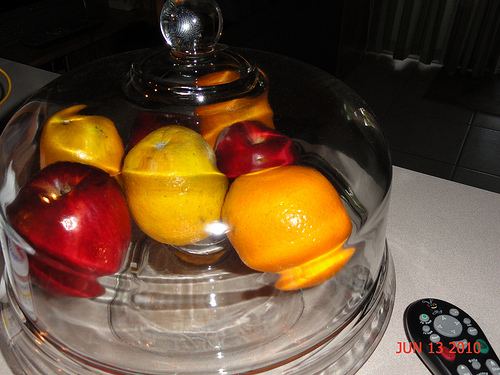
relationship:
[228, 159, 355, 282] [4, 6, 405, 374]
fruit in bowl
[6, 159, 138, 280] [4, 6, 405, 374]
fruit in bowl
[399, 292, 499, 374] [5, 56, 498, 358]
remote on table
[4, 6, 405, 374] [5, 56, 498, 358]
bowl on table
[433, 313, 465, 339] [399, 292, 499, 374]
button on remote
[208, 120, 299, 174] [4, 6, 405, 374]
apple in bowl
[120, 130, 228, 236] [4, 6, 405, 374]
orange in bowl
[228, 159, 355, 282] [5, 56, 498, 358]
fruit on table